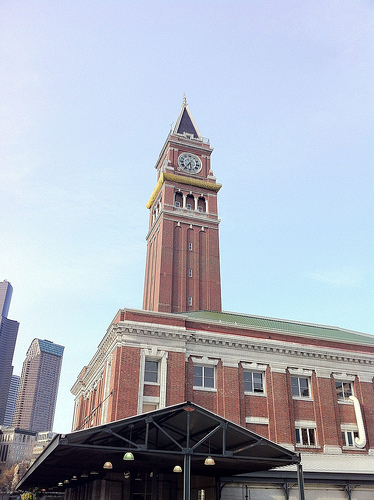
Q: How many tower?
A: 1.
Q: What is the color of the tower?
A: Red.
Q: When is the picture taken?
A: Daytime.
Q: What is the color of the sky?
A: Blue.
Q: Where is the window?
A: In the wall of the building.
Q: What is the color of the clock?
A: Black and white.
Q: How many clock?
A: One.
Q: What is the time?
A: 5:35.